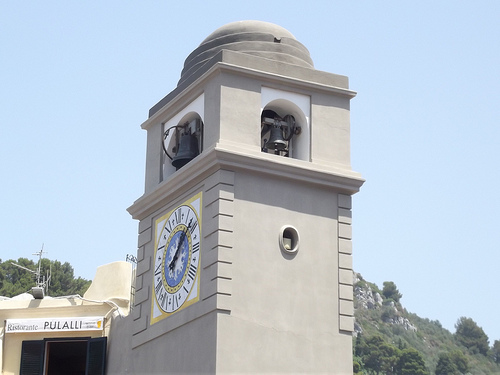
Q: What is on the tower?
A: Clock.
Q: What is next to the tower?
A: A building.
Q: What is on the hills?
A: Trees.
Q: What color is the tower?
A: Light gray.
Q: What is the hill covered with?
A: Trees.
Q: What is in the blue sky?
A: Clouds.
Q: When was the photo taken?
A: Daytime.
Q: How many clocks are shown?
A: One.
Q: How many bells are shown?
A: Two.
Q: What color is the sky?
A: Blue.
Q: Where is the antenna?
A: Top of building.